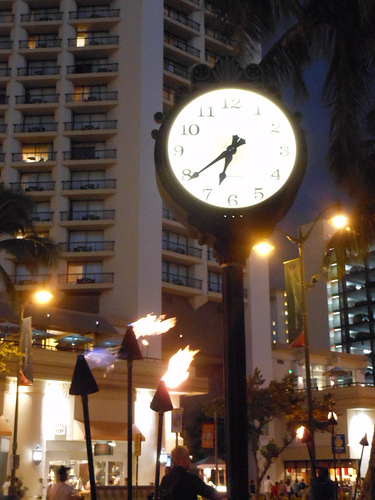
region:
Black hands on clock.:
[182, 131, 250, 204]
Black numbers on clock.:
[167, 96, 290, 215]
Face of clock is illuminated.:
[174, 83, 297, 213]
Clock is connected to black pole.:
[174, 203, 284, 497]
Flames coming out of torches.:
[64, 308, 216, 393]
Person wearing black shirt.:
[156, 461, 204, 498]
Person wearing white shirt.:
[45, 485, 79, 496]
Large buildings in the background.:
[247, 268, 364, 473]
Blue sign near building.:
[324, 427, 347, 466]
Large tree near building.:
[199, 392, 331, 470]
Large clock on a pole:
[127, 72, 363, 303]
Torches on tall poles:
[58, 303, 184, 448]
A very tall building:
[0, 19, 165, 319]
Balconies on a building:
[49, 227, 124, 291]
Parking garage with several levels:
[302, 247, 369, 369]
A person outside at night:
[153, 427, 221, 493]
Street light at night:
[9, 276, 57, 317]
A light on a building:
[22, 435, 49, 474]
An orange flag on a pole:
[195, 410, 218, 460]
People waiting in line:
[255, 469, 308, 493]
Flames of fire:
[69, 306, 210, 409]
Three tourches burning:
[58, 292, 190, 498]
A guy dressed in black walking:
[150, 434, 234, 498]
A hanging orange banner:
[195, 414, 224, 452]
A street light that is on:
[1, 281, 64, 496]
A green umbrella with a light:
[54, 323, 93, 354]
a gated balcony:
[157, 263, 211, 293]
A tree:
[223, 380, 303, 496]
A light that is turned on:
[26, 442, 46, 469]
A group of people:
[254, 468, 310, 498]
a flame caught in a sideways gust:
[134, 315, 174, 334]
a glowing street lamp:
[32, 445, 43, 464]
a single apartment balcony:
[13, 83, 59, 108]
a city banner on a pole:
[282, 262, 308, 347]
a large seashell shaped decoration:
[215, 55, 243, 85]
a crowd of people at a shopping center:
[265, 475, 307, 495]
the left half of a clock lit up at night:
[155, 89, 234, 213]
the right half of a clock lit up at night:
[229, 88, 306, 208]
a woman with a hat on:
[49, 465, 72, 499]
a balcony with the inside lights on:
[12, 138, 55, 162]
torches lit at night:
[69, 301, 198, 452]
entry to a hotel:
[32, 443, 140, 497]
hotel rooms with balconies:
[7, 2, 117, 293]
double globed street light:
[247, 203, 364, 425]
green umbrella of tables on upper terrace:
[23, 324, 132, 354]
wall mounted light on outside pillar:
[6, 377, 51, 499]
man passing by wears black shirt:
[156, 441, 221, 498]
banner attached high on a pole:
[278, 256, 314, 353]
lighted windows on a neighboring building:
[323, 241, 374, 359]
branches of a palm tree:
[0, 182, 65, 307]